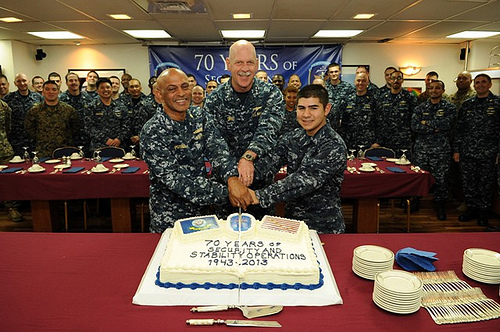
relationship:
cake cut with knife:
[155, 212, 324, 291] [237, 206, 242, 245]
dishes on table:
[351, 243, 499, 315] [1, 231, 499, 331]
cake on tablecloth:
[155, 212, 324, 291] [1, 233, 498, 331]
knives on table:
[185, 304, 284, 331] [1, 231, 499, 331]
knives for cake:
[185, 304, 284, 331] [155, 212, 324, 291]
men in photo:
[0, 38, 498, 233] [1, 2, 497, 331]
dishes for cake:
[351, 243, 499, 315] [155, 212, 324, 291]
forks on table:
[413, 270, 500, 326] [1, 231, 499, 331]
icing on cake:
[155, 266, 323, 291] [155, 212, 324, 291]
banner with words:
[143, 42, 347, 90] [195, 53, 297, 84]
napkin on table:
[395, 246, 439, 271] [1, 231, 499, 331]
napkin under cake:
[132, 227, 343, 308] [155, 212, 324, 291]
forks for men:
[413, 270, 500, 326] [0, 38, 498, 233]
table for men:
[0, 157, 435, 199] [0, 38, 498, 233]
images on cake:
[180, 213, 303, 238] [155, 212, 324, 291]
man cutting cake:
[203, 40, 285, 216] [155, 212, 324, 291]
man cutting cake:
[139, 68, 253, 234] [155, 212, 324, 291]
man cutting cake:
[248, 84, 347, 233] [155, 212, 324, 291]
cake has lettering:
[155, 212, 324, 291] [190, 239, 308, 266]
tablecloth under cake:
[1, 233, 498, 331] [155, 212, 324, 291]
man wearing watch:
[203, 40, 285, 216] [241, 153, 255, 161]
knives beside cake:
[185, 304, 284, 331] [155, 212, 324, 291]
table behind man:
[0, 157, 435, 199] [203, 40, 285, 216]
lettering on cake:
[190, 239, 308, 266] [155, 212, 324, 291]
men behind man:
[0, 38, 498, 233] [203, 40, 285, 216]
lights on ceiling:
[0, 12, 499, 41] [0, 0, 498, 46]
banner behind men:
[143, 42, 347, 90] [0, 38, 498, 233]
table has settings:
[0, 157, 435, 199] [1, 147, 425, 174]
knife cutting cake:
[237, 206, 242, 245] [155, 212, 324, 291]